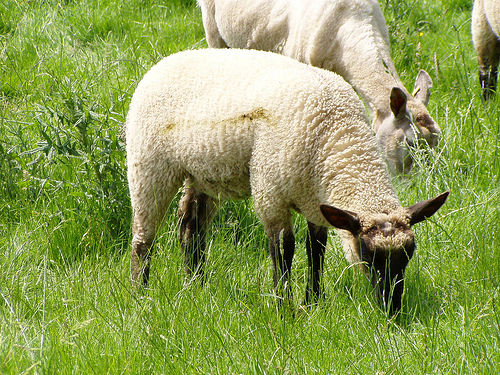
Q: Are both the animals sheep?
A: Yes, all the animals are sheep.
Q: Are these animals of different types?
A: No, all the animals are sheep.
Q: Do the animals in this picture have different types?
A: No, all the animals are sheep.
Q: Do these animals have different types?
A: No, all the animals are sheep.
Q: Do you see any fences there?
A: No, there are no fences.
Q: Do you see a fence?
A: No, there are no fences.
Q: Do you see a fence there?
A: No, there are no fences.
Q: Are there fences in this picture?
A: No, there are no fences.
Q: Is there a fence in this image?
A: No, there are no fences.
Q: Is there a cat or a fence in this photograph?
A: No, there are no fences or cats.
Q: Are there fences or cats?
A: No, there are no fences or cats.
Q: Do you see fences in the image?
A: No, there are no fences.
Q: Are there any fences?
A: No, there are no fences.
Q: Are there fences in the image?
A: No, there are no fences.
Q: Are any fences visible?
A: No, there are no fences.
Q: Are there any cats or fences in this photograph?
A: No, there are no fences or cats.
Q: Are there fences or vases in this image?
A: No, there are no fences or vases.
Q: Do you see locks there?
A: No, there are no locks.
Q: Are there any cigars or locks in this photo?
A: No, there are no locks or cigars.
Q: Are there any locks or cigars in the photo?
A: No, there are no locks or cigars.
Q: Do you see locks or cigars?
A: No, there are no locks or cigars.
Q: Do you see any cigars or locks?
A: No, there are no locks or cigars.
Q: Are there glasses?
A: No, there are no glasses.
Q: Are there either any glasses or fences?
A: No, there are no glasses or fences.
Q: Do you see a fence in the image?
A: No, there are no fences.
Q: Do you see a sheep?
A: Yes, there is a sheep.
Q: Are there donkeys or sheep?
A: Yes, there is a sheep.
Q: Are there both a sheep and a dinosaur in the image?
A: No, there is a sheep but no dinosaurs.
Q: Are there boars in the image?
A: No, there are no boars.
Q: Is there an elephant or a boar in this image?
A: No, there are no boars or elephants.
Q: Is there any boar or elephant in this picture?
A: No, there are no boars or elephants.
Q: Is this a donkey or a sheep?
A: This is a sheep.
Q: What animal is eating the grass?
A: The sheep is eating the grass.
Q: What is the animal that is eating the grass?
A: The animal is a sheep.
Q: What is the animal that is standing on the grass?
A: The animal is a sheep.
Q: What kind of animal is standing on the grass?
A: The animal is a sheep.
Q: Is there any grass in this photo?
A: Yes, there is grass.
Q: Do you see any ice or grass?
A: Yes, there is grass.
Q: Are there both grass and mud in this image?
A: No, there is grass but no mud.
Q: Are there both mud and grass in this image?
A: No, there is grass but no mud.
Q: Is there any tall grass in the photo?
A: Yes, there is tall grass.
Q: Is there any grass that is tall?
A: Yes, there is grass that is tall.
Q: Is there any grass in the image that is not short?
A: Yes, there is tall grass.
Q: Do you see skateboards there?
A: No, there are no skateboards.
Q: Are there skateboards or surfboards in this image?
A: No, there are no skateboards or surfboards.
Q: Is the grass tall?
A: Yes, the grass is tall.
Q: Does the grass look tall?
A: Yes, the grass is tall.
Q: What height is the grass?
A: The grass is tall.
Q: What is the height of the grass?
A: The grass is tall.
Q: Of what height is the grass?
A: The grass is tall.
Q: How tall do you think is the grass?
A: The grass is tall.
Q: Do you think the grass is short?
A: No, the grass is tall.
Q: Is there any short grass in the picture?
A: No, there is grass but it is tall.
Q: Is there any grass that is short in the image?
A: No, there is grass but it is tall.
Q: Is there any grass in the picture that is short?
A: No, there is grass but it is tall.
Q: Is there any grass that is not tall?
A: No, there is grass but it is tall.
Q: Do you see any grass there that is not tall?
A: No, there is grass but it is tall.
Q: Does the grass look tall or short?
A: The grass is tall.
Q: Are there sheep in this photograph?
A: Yes, there is a sheep.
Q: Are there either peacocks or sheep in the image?
A: Yes, there is a sheep.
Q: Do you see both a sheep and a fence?
A: No, there is a sheep but no fences.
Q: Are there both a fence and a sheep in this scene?
A: No, there is a sheep but no fences.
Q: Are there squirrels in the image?
A: No, there are no squirrels.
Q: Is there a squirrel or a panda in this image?
A: No, there are no squirrels or pandas.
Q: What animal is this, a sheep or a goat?
A: This is a sheep.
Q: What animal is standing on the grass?
A: The animal is a sheep.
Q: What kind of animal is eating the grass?
A: The animal is a sheep.